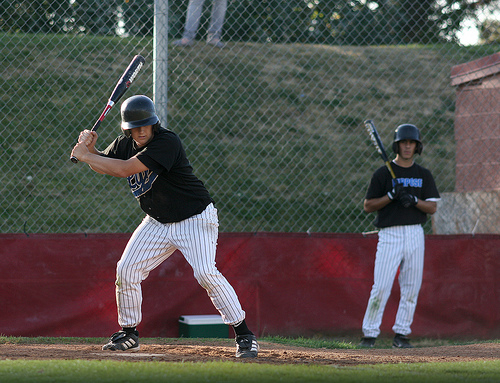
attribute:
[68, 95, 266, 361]
man — on deck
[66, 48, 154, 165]
baseball bat — aluminum, black, red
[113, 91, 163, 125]
helmet — black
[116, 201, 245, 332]
jersey pants — striped, gray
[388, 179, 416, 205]
gloves — black, white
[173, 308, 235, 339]
chest — green, white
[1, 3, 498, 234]
fence — here, metal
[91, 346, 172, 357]
pad — here, white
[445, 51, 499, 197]
small building — here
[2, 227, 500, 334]
trim — red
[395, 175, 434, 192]
writing — blue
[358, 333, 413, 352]
shoes — black, white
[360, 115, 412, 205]
baseball bat — black, gold